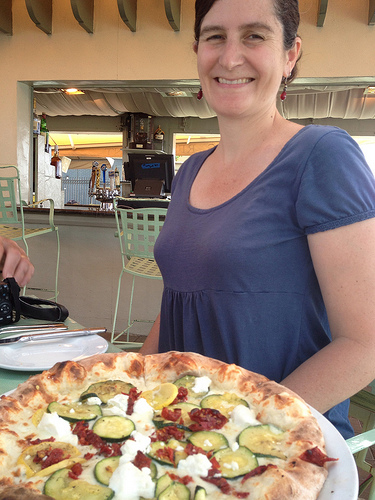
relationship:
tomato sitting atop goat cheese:
[42, 384, 319, 494] [19, 381, 250, 490]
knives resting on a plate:
[3, 316, 108, 342] [0, 319, 108, 374]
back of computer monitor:
[134, 178, 164, 199] [130, 179, 173, 204]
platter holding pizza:
[303, 387, 363, 500] [2, 348, 325, 500]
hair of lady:
[188, 1, 303, 91] [119, 0, 372, 438]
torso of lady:
[158, 283, 325, 415] [119, 0, 372, 438]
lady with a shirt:
[119, 0, 372, 438] [149, 120, 375, 412]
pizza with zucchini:
[2, 348, 325, 500] [34, 376, 281, 500]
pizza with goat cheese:
[2, 348, 325, 500] [19, 381, 250, 490]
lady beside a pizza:
[119, 0, 372, 438] [2, 348, 325, 500]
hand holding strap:
[4, 233, 34, 293] [4, 277, 75, 337]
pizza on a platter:
[2, 348, 325, 500] [303, 387, 363, 500]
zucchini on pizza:
[34, 376, 281, 500] [2, 348, 325, 500]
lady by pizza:
[119, 0, 372, 438] [2, 348, 325, 500]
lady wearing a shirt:
[119, 0, 372, 438] [149, 120, 375, 412]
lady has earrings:
[119, 0, 372, 438] [195, 79, 291, 102]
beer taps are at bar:
[87, 159, 123, 199] [18, 195, 171, 226]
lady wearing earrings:
[119, 0, 372, 438] [195, 79, 291, 102]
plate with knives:
[0, 319, 108, 374] [3, 316, 108, 342]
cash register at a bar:
[123, 157, 172, 202] [18, 195, 171, 226]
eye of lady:
[244, 33, 270, 45] [119, 0, 372, 438]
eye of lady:
[204, 32, 227, 42] [119, 0, 372, 438]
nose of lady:
[216, 48, 247, 74] [119, 0, 372, 438]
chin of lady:
[208, 96, 257, 116] [119, 0, 372, 438]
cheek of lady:
[250, 46, 279, 72] [119, 0, 372, 438]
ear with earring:
[282, 38, 304, 100] [282, 80, 287, 103]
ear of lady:
[282, 38, 304, 100] [119, 0, 372, 438]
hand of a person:
[4, 233, 34, 293] [3, 214, 41, 304]